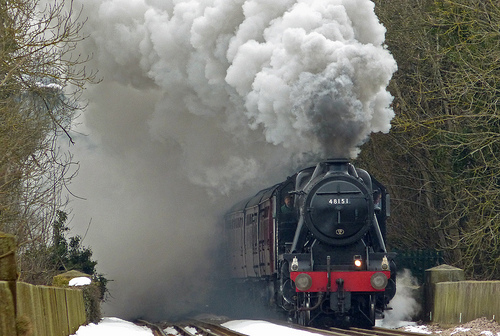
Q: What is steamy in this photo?
A: The train.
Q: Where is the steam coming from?
A: The train.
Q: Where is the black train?
A: On rails.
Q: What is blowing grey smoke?
A: Black train.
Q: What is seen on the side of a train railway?
A: Trees.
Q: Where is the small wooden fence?
A: On side of train rails.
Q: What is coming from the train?
A: Gray plume of smoke.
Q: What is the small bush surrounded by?
A: Smoke.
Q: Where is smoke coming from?
A: Train.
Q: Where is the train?
A: On train tracks.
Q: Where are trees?
A: On both sides of the tracks.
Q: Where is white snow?
A: On the ground.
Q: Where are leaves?
A: On trees.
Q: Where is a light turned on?
A: Front of the train.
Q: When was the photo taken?
A: Daytime.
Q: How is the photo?
A: Clear.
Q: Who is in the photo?
A: Nobody.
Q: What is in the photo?
A: A train.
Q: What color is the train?
A: Black.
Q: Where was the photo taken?
A: On the railroad.